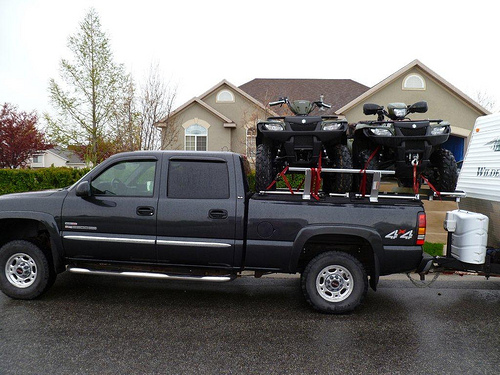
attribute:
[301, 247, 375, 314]
tire — black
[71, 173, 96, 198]
mirror — black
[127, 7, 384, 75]
sky — grey, cloudy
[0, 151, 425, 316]
truck — black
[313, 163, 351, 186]
straps — red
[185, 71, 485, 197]
walls — tan